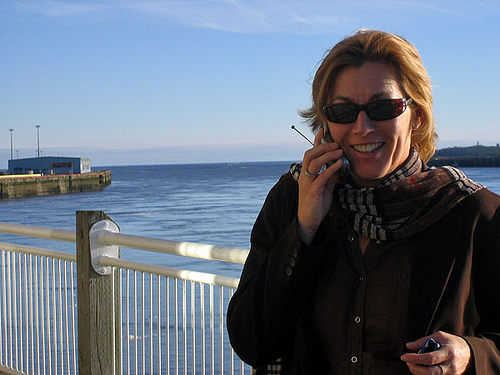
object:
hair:
[296, 27, 441, 166]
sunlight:
[175, 237, 216, 291]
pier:
[0, 171, 113, 201]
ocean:
[0, 161, 500, 184]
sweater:
[223, 171, 499, 373]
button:
[359, 277, 364, 281]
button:
[354, 316, 361, 324]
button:
[350, 356, 358, 364]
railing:
[0, 222, 252, 292]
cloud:
[193, 7, 285, 34]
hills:
[432, 144, 499, 165]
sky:
[0, 0, 500, 167]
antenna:
[290, 125, 315, 145]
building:
[7, 156, 90, 175]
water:
[1, 161, 497, 373]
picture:
[0, 0, 498, 375]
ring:
[304, 167, 318, 178]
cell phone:
[290, 125, 351, 176]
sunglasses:
[322, 98, 414, 126]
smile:
[343, 141, 391, 161]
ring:
[439, 364, 446, 374]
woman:
[226, 28, 498, 373]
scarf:
[288, 147, 489, 246]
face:
[327, 74, 406, 178]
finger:
[311, 158, 343, 192]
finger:
[400, 348, 449, 365]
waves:
[129, 175, 277, 249]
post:
[74, 209, 123, 374]